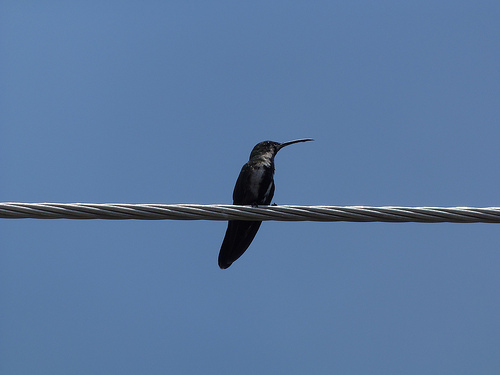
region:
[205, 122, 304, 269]
bird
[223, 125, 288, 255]
black bird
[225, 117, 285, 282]
bird sitting on wire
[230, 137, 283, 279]
black bird sitting on wire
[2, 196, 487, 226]
silver wire under black bird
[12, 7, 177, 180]
blue sky with no clouds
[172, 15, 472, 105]
blue sky with no clouds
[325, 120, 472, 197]
blue sky with no clouds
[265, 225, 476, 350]
blue sky with no clouds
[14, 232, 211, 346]
blue sky with no clouds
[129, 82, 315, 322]
a bird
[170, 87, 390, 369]
a bird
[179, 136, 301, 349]
a bird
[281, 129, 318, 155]
a long bird's beak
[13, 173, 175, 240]
a section of rope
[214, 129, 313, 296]
a bird on a rope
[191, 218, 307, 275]
tail feathers of a bird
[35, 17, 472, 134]
a clear blue sky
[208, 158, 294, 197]
a section of light feathers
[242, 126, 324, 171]
the head of a bird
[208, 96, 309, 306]
a bird looking right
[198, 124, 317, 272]
a two toned bird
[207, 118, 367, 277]
a perching bird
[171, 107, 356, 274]
A bird on a wire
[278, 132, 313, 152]
Long black beak of bird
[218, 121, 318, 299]
A black bird is sitting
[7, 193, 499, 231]
A coiled silver wire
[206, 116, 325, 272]
A black bird on a silver wire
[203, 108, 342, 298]
One bird, one wire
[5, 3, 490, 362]
A clear blue sky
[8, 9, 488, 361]
A cloudless blue sky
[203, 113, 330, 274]
A shiny black bird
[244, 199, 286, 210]
Two small feet of bird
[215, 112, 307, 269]
black bird alone black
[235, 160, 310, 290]
black bird alone black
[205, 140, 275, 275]
black bird alone black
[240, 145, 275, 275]
black bird alone black